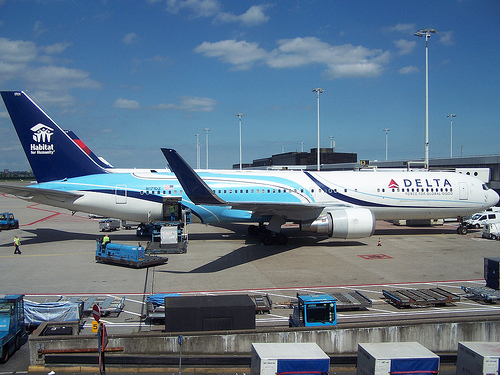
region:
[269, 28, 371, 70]
clouds in the sky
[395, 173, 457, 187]
name of airline carrier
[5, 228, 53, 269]
airline worker on runway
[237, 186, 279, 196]
windows on the airplane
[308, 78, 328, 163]
light on the pole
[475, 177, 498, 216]
nose of the plane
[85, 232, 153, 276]
person on luggage unit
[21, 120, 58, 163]
Habitat sign on airplane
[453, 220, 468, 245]
front wheel on airplane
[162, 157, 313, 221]
wing on the airplane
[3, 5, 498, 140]
Almost clear blue sky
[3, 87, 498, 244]
Blue and white airplane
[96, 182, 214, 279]
People loading supplies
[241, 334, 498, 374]
Pallets of supplies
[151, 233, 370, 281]
Airplane wing's shadow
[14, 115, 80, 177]
Habitat for humanity logo on tail fin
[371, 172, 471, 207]
Plane is owned by Delta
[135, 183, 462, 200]
Passenger seat windows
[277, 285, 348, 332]
Blue loading work truck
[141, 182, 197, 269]
Airplane supplies loading ramp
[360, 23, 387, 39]
part of the sky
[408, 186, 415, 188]
part of a plane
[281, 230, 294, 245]
bottom of a plane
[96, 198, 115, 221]
back of a plane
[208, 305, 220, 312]
edge of a wall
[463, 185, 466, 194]
door of a plane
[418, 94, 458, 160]
part of a plane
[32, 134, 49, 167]
back of a plane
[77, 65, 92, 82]
part of a cloud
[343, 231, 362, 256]
wing of a plane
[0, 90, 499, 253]
THE PLANE IS BLUE AND WHITE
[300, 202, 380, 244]
THIS IS THE ENGINE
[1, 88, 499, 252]
THIS IS THE PLANE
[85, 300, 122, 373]
THIS IS A SIGN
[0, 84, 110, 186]
THIS IS THE TAIL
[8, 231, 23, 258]
THIS IS A MAN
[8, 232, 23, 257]
THE MAN IS WEARING BLACK PANTS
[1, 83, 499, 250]
THIS IS THE WING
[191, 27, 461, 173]
THESE ARE THE LIGHTS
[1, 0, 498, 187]
THIS IS THE CLOUDY SKY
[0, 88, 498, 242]
blue and white airplane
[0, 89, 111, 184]
dark blue airplane tail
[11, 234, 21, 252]
airline worker is walking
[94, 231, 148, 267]
airline worker operating equipment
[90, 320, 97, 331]
small sign is yellow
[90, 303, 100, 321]
round sign is red and white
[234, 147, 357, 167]
terminal has black roof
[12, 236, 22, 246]
airline employee wears yellow shirt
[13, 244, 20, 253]
airline employee wears black pants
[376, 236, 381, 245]
traffic cone on tarmac